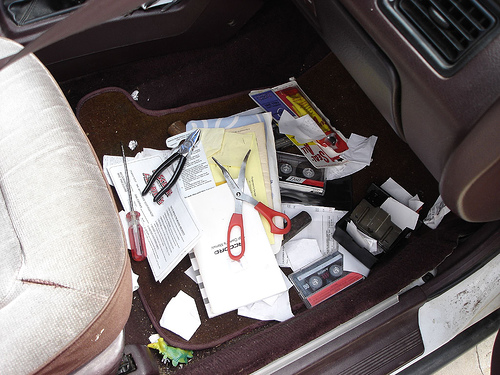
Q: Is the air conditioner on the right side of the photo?
A: Yes, the air conditioner is on the right of the image.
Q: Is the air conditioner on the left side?
A: No, the air conditioner is on the right of the image.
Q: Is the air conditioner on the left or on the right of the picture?
A: The air conditioner is on the right of the image.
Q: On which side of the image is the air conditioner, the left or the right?
A: The air conditioner is on the right of the image.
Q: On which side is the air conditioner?
A: The air conditioner is on the right of the image.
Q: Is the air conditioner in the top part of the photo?
A: Yes, the air conditioner is in the top of the image.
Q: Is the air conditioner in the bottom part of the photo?
A: No, the air conditioner is in the top of the image.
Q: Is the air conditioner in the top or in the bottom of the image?
A: The air conditioner is in the top of the image.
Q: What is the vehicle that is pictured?
A: The vehicle is a car.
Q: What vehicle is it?
A: The vehicle is a car.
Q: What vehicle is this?
A: This is a car.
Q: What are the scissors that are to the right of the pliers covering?
A: The scissors are covering the paper.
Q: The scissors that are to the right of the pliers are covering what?
A: The scissors are covering the paper.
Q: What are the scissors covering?
A: The scissors are covering the paper.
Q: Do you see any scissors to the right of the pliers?
A: Yes, there are scissors to the right of the pliers.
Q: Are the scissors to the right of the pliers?
A: Yes, the scissors are to the right of the pliers.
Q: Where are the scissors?
A: The scissors are on the floor.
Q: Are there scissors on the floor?
A: Yes, there are scissors on the floor.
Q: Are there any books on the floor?
A: No, there are scissors on the floor.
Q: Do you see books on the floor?
A: No, there are scissors on the floor.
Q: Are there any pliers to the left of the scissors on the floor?
A: Yes, there are pliers to the left of the scissors.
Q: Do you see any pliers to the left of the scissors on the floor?
A: Yes, there are pliers to the left of the scissors.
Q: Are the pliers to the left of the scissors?
A: Yes, the pliers are to the left of the scissors.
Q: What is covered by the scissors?
A: The paper is covered by the scissors.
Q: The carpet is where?
A: The carpet is on the floor.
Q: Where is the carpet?
A: The carpet is on the floor.